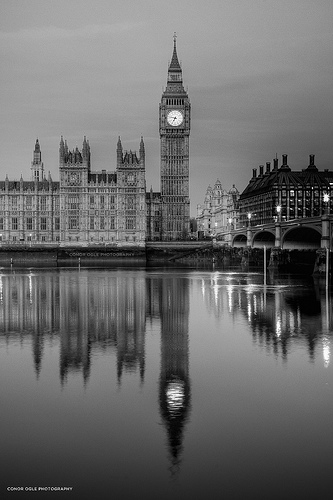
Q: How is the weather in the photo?
A: Fair.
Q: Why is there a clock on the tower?
A: To show the time.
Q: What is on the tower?
A: A clock.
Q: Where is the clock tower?
A: Adjacent to a historical building.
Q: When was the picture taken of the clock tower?
A: During a vacation.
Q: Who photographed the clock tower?
A: Visitor.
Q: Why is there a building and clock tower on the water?
A: A reflection.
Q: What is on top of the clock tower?
A: Steeple.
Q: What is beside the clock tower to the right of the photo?
A: A bridge.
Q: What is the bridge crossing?
A: A river.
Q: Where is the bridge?
A: On the right.